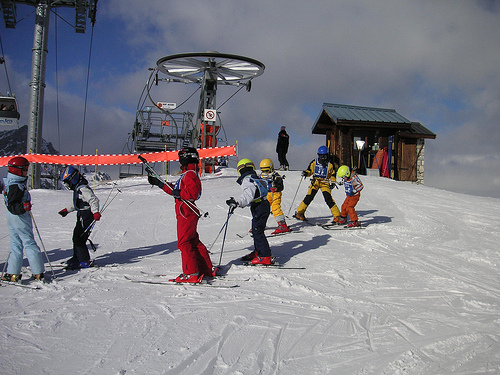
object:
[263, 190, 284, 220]
snowpants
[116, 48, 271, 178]
ski lift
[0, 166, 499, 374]
hill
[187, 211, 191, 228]
red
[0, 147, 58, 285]
child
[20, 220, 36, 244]
blue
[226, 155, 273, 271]
kids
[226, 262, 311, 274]
ski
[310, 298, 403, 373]
ski tracks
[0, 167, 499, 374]
snow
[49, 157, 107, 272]
kid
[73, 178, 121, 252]
ski poles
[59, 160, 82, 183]
helmet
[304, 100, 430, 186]
shack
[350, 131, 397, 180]
ski equipment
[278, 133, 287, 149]
black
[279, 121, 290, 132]
helmet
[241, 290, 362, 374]
ski marks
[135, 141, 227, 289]
skier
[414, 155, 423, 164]
stones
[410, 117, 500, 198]
puffy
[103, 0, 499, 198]
clouds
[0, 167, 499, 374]
group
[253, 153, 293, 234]
skier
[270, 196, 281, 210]
yellow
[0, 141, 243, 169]
banner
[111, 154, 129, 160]
orange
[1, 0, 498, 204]
blue sky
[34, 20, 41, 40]
metal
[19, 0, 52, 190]
pole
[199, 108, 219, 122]
white sign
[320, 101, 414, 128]
shingled roof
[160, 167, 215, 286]
red snowsuit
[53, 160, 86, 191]
head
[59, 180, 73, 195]
down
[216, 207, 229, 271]
long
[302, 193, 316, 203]
knees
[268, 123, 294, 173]
person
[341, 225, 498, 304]
line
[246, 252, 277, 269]
ski boots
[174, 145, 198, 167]
ski helmet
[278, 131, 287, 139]
supervising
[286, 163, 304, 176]
top